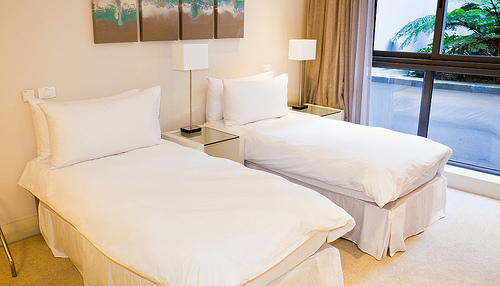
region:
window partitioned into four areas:
[354, 2, 499, 177]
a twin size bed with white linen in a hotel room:
[208, 73, 451, 255]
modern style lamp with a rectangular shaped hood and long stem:
[176, 41, 208, 136]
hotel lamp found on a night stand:
[289, 38, 314, 111]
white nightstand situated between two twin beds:
[161, 123, 243, 172]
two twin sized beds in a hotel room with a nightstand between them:
[23, 71, 450, 284]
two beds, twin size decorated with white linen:
[29, 71, 452, 284]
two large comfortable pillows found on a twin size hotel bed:
[28, 84, 162, 169]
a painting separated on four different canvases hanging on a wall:
[91, 0, 247, 44]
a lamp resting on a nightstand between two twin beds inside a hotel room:
[158, 40, 241, 163]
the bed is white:
[49, 104, 346, 284]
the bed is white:
[260, 119, 443, 199]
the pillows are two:
[43, 95, 175, 167]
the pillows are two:
[209, 70, 296, 120]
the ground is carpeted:
[448, 224, 494, 283]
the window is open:
[316, 5, 499, 159]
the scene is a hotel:
[11, 13, 483, 280]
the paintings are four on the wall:
[85, 8, 258, 49]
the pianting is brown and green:
[93, 1, 147, 57]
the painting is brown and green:
[144, 5, 176, 40]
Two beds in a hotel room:
[17, 58, 465, 283]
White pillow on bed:
[23, 76, 177, 170]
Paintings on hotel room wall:
[76, 0, 266, 51]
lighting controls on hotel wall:
[17, 78, 61, 106]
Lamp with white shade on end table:
[167, 35, 216, 135]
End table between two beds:
[159, 119, 247, 167]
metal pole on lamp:
[186, 66, 196, 126]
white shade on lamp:
[169, 39, 213, 74]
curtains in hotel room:
[314, 0, 378, 118]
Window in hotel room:
[350, 2, 495, 123]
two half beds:
[4, 102, 455, 285]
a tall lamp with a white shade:
[290, 19, 327, 117]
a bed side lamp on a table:
[170, 34, 216, 134]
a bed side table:
[168, 123, 244, 165]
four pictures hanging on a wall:
[68, 2, 262, 53]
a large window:
[318, 26, 482, 143]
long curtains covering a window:
[301, 10, 391, 125]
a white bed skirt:
[361, 176, 448, 268]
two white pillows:
[28, 83, 173, 175]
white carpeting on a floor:
[442, 227, 491, 283]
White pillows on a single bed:
[28, 83, 167, 167]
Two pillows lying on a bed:
[205, 70, 295, 126]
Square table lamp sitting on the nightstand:
[168, 40, 210, 136]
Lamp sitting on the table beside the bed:
[288, 38, 316, 110]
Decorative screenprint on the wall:
[90, 0, 243, 42]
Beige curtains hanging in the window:
[304, 0, 375, 130]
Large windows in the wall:
[367, 0, 499, 179]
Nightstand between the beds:
[162, 123, 244, 165]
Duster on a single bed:
[307, 173, 449, 259]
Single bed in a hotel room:
[204, 70, 448, 262]